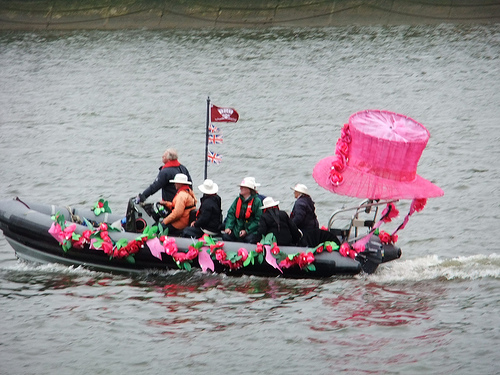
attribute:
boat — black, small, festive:
[0, 188, 403, 282]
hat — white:
[170, 173, 193, 186]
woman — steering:
[160, 173, 195, 233]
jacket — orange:
[164, 194, 196, 232]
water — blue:
[0, 25, 495, 374]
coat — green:
[224, 199, 262, 240]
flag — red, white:
[210, 102, 239, 127]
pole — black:
[205, 93, 213, 187]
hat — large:
[310, 109, 446, 200]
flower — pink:
[166, 240, 177, 254]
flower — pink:
[65, 225, 76, 238]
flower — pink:
[339, 242, 349, 256]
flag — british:
[208, 151, 223, 165]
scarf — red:
[163, 158, 180, 171]